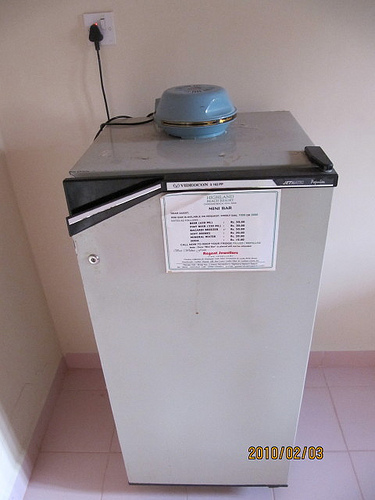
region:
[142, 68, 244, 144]
baby blue popcorn maker on top of min fridge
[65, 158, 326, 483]
black and white miniature refrigerator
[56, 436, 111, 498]
white square tile on the floor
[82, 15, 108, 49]
black plug in white socket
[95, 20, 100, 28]
red button attached to black plug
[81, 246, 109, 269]
silver metal lock on refrigerator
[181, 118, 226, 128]
metal seal on blue popcorn maker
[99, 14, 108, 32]
white switch on white outlet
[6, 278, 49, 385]
white wall next to white refrigerator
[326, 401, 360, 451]
gray line in white tile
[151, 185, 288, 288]
paper is stick on the fridge.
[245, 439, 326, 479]
2010/02/03 is the date on the picture.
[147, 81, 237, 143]
Blue color stabilizer.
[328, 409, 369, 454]
Floor is white.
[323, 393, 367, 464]
Floor is made of tiles.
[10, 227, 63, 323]
wall is white in color.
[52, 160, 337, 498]
Fridge is black and white in color.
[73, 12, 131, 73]
Switch is fixed to the wall.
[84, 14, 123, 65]
Plug is black in color.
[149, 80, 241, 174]
Stabilizer is kept on the top of the fridge.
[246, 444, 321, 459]
Yellow date time stamp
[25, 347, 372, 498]
White tile floor in the kitchen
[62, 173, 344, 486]
Grey and black refrigerator door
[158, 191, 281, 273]
Sign on the refrigerator door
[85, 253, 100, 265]
A silver key hole on the door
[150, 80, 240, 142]
A light blue appliance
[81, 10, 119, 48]
A white electricity socket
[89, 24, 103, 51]
A black plug plugged in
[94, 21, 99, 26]
A red power indicator light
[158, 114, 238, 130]
Gold colored trim on the blue appliance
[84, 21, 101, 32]
orange tip of black electrical outlet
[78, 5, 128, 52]
white square electrical outlet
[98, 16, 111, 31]
white switch on electrical outlet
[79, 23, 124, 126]
long black electrical cord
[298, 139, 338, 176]
large black fastener on refridgerator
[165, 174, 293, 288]
white square logo on refridgerator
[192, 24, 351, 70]
large portion of white wall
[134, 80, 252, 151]
blue appliance on top of refridgerator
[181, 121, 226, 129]
silver base of blue appliance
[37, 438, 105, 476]
white tiles on white floor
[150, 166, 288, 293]
Paper is stick on the fridge.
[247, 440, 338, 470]
2010/02/03 is the date in the picture.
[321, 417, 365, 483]
floor is white color.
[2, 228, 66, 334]
Wall is white in color.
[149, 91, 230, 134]
Stabilizer is blue in color.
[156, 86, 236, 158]
Stabilizer is on top of the fridge.